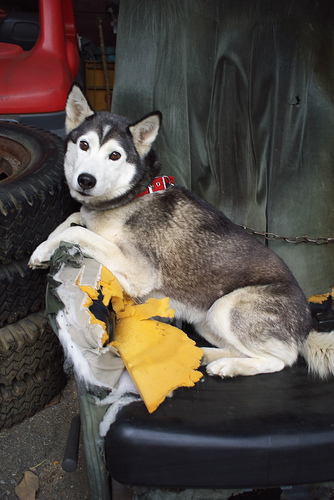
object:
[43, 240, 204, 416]
fabric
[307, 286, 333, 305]
fabric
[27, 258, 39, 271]
paw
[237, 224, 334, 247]
chain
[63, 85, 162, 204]
head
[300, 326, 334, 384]
tail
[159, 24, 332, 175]
wall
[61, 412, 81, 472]
arm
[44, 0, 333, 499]
chair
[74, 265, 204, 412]
inside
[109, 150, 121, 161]
eye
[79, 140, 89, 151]
eye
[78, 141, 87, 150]
right eye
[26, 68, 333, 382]
dog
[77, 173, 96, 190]
mouth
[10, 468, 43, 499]
leaf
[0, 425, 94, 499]
ground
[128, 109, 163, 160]
dog's ear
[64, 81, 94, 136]
dog's ear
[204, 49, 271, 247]
shape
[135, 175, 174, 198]
collar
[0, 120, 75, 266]
tire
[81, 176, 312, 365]
body